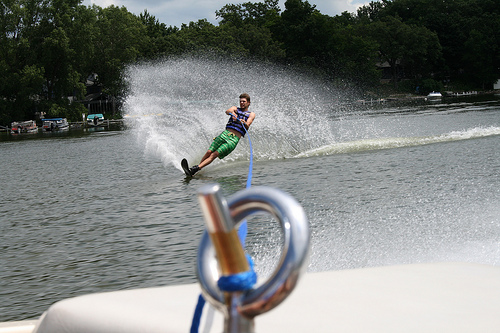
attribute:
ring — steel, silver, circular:
[192, 179, 312, 320]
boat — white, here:
[2, 261, 499, 332]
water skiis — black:
[177, 155, 197, 180]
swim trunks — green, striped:
[205, 127, 239, 161]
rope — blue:
[188, 112, 259, 332]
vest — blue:
[226, 105, 252, 137]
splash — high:
[113, 49, 390, 174]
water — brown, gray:
[1, 96, 500, 321]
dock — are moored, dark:
[0, 115, 124, 134]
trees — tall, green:
[0, 0, 498, 124]